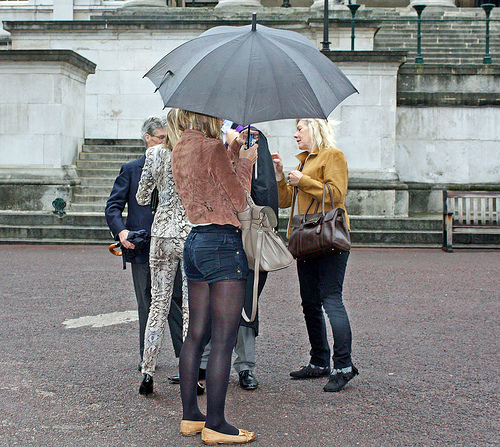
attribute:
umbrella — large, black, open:
[143, 11, 358, 147]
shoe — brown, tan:
[201, 425, 254, 443]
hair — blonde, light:
[173, 106, 223, 140]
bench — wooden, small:
[443, 187, 499, 252]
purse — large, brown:
[287, 182, 350, 259]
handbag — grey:
[236, 188, 294, 322]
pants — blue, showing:
[297, 249, 351, 375]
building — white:
[1, 1, 500, 251]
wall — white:
[0, 49, 98, 184]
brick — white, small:
[33, 104, 67, 135]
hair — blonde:
[299, 118, 342, 154]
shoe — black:
[323, 366, 359, 391]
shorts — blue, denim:
[183, 226, 248, 285]